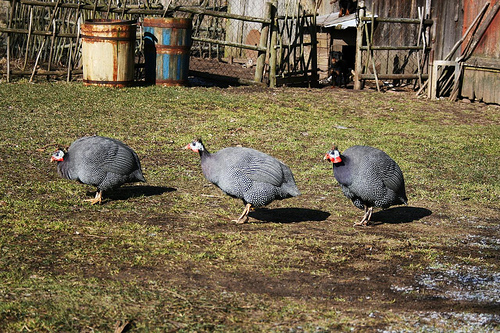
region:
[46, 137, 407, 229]
three guinea hens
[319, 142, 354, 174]
guinea hens have red on their heads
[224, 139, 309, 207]
guinea hens have grey wings and bodies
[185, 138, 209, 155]
white on the guinea hen's face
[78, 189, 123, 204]
guinea hen has orangish tan feet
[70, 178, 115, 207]
guinea hens are in the grass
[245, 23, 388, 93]
gate is open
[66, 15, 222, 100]
two trash cans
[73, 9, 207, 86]
trash cans are rusty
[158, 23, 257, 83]
trash can is against the fence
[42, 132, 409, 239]
Turkeys in the photo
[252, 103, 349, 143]
Grass in the photo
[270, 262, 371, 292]
Bare ground in the photo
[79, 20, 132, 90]
Small tanks in the photo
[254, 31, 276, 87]
Wooden poles in the photo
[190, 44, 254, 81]
Mesh wire fence in the photo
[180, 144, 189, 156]
Brown beak in the photo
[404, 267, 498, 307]
White cereals in the photo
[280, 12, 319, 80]
A gate in the photo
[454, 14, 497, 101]
A wall in the photo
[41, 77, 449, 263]
Three turkeys are walking together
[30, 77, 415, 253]
The turkeys are looking for food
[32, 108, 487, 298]
The turkeys are on a farm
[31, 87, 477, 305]
The turkeys are looking for their young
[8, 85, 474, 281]
The turkeys are in a backyard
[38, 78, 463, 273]
The turkeys are all males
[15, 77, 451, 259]
The turkeys are watching for predators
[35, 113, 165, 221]
A turkey is walking slowly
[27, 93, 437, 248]
Two turkeys are following another turkey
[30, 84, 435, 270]
The turkeys are all brothers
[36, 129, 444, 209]
three ginney chickens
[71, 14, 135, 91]
a rusted garbage can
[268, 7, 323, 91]
a wood gate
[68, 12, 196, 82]
two rusted barrels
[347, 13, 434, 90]
a wood fence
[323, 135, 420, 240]
a ginney chicken with a red face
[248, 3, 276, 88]
a wood post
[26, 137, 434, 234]
ginney chickens in a field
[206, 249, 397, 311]
patches of grass and mud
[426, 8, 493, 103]
pieces of wood leaning against a building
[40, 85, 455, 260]
The turkeys all have colorful plumage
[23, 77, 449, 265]
The birds are on a turkey farm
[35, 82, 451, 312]
The birds are following each other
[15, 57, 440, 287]
The birds are looking for food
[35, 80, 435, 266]
The birds are hunting for worms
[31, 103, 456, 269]
The birds are all sisters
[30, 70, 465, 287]
The birds are walking in the grass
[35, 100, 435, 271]
The birds are out in the daytime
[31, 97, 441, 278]
The birds are walking very quickly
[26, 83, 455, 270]
The birds are staying close together